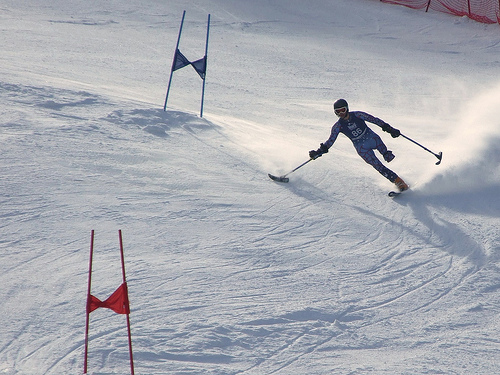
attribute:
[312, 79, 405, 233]
man — skiing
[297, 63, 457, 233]
man — skiing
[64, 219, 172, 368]
poles — red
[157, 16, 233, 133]
poles — blue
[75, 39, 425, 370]
race course — downhill skiing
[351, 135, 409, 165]
leg — missing part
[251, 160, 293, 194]
skiis — small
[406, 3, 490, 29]
fence — mesh, orange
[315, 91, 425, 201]
person — skiing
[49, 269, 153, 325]
flag — red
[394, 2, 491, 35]
fence — red, safety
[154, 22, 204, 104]
flag — blue